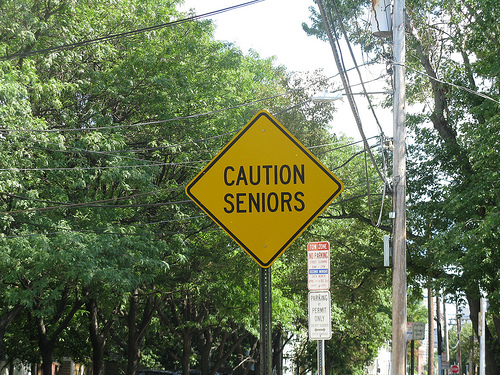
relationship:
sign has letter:
[204, 98, 328, 246] [221, 152, 240, 190]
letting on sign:
[186, 123, 366, 216] [204, 98, 328, 246]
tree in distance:
[36, 57, 198, 332] [61, 35, 458, 340]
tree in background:
[36, 57, 198, 332] [35, 51, 479, 137]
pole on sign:
[238, 265, 291, 362] [204, 98, 328, 246]